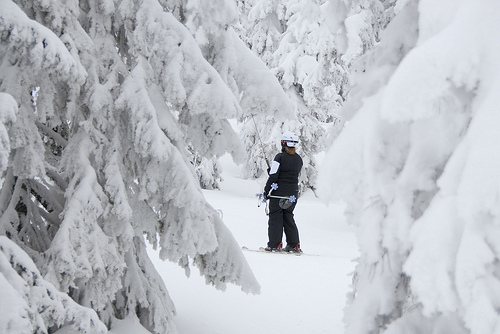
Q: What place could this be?
A: It is a forest.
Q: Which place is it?
A: It is a forest.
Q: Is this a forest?
A: Yes, it is a forest.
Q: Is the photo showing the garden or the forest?
A: It is showing the forest.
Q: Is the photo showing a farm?
A: No, the picture is showing a forest.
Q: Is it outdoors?
A: Yes, it is outdoors.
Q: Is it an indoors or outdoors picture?
A: It is outdoors.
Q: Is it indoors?
A: No, it is outdoors.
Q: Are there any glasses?
A: No, there are no glasses.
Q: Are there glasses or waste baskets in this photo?
A: No, there are no glasses or waste baskets.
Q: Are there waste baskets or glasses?
A: No, there are no glasses or waste baskets.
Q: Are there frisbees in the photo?
A: No, there are no frisbees.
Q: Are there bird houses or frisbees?
A: No, there are no frisbees or bird houses.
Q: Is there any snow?
A: Yes, there is snow.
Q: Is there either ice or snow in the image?
A: Yes, there is snow.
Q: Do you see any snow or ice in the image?
A: Yes, there is snow.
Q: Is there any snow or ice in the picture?
A: Yes, there is snow.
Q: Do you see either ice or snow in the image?
A: Yes, there is snow.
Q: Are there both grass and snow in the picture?
A: No, there is snow but no grass.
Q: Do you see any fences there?
A: No, there are no fences.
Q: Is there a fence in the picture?
A: No, there are no fences.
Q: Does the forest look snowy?
A: Yes, the forest is snowy.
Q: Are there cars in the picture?
A: No, there are no cars.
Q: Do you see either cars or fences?
A: No, there are no cars or fences.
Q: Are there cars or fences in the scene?
A: No, there are no cars or fences.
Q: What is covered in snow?
A: The trees are covered in snow.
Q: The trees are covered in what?
A: The trees are covered in snow.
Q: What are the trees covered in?
A: The trees are covered in snow.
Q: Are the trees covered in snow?
A: Yes, the trees are covered in snow.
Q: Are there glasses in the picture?
A: No, there are no glasses.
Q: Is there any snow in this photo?
A: Yes, there is snow.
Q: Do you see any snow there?
A: Yes, there is snow.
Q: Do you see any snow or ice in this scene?
A: Yes, there is snow.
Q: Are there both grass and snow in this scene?
A: No, there is snow but no grass.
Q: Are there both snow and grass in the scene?
A: No, there is snow but no grass.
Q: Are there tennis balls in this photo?
A: No, there are no tennis balls.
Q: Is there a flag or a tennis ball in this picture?
A: No, there are no tennis balls or flags.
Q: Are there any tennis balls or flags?
A: No, there are no tennis balls or flags.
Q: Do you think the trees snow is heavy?
A: Yes, the snow is heavy.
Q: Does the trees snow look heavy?
A: Yes, the snow is heavy.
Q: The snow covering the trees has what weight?
A: The snow is heavy.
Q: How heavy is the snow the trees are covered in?
A: The snow is heavy.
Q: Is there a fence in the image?
A: No, there are no fences.